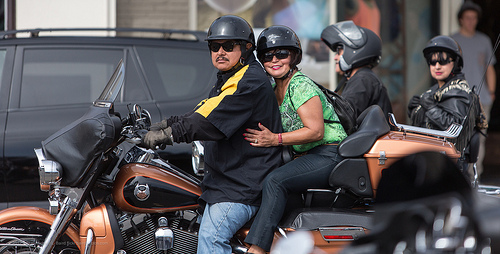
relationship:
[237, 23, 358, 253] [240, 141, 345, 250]
passenger wearing jeans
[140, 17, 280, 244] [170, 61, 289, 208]
man in a shirt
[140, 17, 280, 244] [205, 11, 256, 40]
man wearing a helmet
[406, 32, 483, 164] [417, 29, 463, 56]
person wearing a helmet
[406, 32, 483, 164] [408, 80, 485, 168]
person in jacket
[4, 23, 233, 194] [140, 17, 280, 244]
car behind the man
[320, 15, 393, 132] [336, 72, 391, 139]
man in a jacket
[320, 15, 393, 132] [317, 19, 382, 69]
man wearing a helmet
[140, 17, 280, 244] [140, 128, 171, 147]
man wearing gloves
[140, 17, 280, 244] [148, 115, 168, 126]
man wearing gloves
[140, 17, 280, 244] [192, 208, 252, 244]
man in jeans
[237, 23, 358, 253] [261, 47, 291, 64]
passenger in sunglasses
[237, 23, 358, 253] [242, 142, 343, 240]
passenger wearing jeans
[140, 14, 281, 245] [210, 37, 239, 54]
man in sunglasses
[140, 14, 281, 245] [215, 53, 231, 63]
man with a mustache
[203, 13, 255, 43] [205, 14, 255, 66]
helmet on head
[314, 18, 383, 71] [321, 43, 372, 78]
helmet on head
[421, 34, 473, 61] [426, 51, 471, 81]
helmet on head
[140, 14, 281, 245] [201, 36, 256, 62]
man wearing sunglasses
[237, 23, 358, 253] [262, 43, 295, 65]
passenger wearing sunglasses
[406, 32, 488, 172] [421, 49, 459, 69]
person wearing sunglasses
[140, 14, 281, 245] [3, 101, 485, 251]
man on motorcycle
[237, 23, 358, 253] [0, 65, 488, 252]
passenger on motorcycle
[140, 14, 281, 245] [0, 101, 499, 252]
man driving bike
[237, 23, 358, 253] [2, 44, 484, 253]
passenger on motorcycle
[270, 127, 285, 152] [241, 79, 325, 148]
bracelet on arm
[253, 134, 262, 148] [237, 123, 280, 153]
ring on hand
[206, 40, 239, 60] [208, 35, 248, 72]
sunglasses on face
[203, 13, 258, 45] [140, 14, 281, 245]
helmet on man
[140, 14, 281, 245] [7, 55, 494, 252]
man driving bike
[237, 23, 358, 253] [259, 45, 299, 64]
passenger wearing sunglasses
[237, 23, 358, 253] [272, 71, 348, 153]
passenger wearing blouse